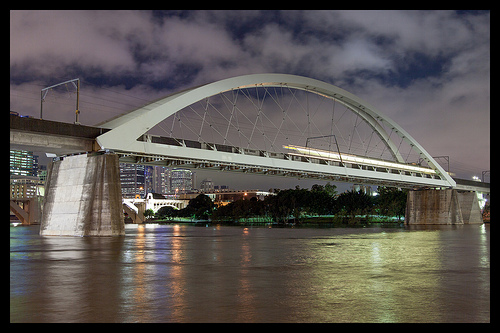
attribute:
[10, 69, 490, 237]
bridge — white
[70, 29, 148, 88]
clouds — white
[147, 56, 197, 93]
sky — blue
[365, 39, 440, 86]
clouds — white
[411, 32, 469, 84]
clouds — white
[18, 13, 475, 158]
sky — blue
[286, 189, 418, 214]
trees — lush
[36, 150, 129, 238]
support — wide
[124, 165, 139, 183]
windows — illuminated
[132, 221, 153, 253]
lighting — orange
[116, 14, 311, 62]
clouds — wispy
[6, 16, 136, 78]
clouds — fluffy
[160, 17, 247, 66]
clouds — fluffy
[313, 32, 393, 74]
clouds — fluffy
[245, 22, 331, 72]
clouds — fluffy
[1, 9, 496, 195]
sky — blue, dark, white, dark blue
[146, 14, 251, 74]
cloud — white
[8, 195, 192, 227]
bridge — stone, distant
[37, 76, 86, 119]
structure — metal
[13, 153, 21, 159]
window — illuminated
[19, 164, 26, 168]
window — illuminated